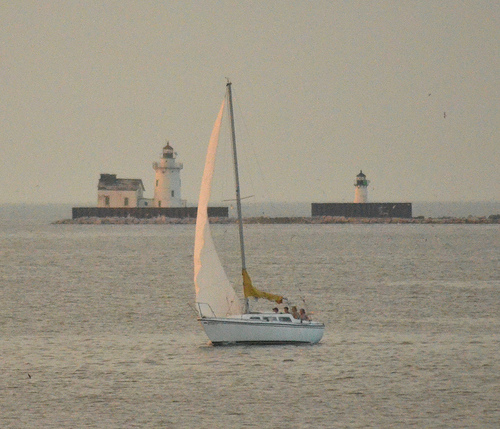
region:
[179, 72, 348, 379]
A lone white boat sailing in the ocean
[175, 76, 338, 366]
A small white sail boat in the water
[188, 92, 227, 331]
A large white wind sail on the boat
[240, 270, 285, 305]
A yellow flag hanging from the metal pole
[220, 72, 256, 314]
A tall metal pole on the boat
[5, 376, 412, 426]
The water looks extremely calm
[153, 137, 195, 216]
A large white lighthouse on the shore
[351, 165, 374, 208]
A smaller white lighthouse on the land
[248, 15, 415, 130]
The sky looks grey and empty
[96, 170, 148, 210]
A small stone house by the lighthouse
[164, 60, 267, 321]
Very tall white sail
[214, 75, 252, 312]
Very tall metal pole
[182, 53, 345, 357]
White sailboat in the water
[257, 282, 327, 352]
People on a boat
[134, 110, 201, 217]
White light house in land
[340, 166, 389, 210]
Small white light house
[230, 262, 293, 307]
Yellow flag on a pole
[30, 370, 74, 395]
Ripples in the water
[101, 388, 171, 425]
Ripples in the water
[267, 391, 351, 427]
Ripples in the water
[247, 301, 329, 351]
four people in a boat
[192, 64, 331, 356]
sailboat on the water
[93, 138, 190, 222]
lighthouse next to keepers house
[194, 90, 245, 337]
mast and white sail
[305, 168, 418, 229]
lighthouse on strip of land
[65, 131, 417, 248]
two lighthouses and lighthouse keepers house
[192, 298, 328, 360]
white boat on the water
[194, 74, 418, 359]
lighthouse behind a sailboat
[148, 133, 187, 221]
lighthouse with three windows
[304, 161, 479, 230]
lighthouse and horizon line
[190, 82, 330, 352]
A boat in the water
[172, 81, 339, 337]
The boat is white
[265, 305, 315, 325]
People are in the boat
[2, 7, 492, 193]
Gray, calm looking sky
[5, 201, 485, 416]
Calm gray looking sea water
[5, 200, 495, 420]
The sea has little ripples in it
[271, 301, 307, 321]
The amount of people are four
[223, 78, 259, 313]
A pole on the boat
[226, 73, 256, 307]
the pole is silver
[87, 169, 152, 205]
A white looking building near the boat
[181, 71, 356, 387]
this is a yatch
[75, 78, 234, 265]
this is a building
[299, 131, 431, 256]
this is a building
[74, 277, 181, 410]
the yacht is in water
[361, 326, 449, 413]
the yacht is in water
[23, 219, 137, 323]
the yacht is in water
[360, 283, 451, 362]
the yacht is in water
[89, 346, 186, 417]
the yacht is in water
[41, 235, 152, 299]
the yacht is in water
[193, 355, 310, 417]
the yacht is in water